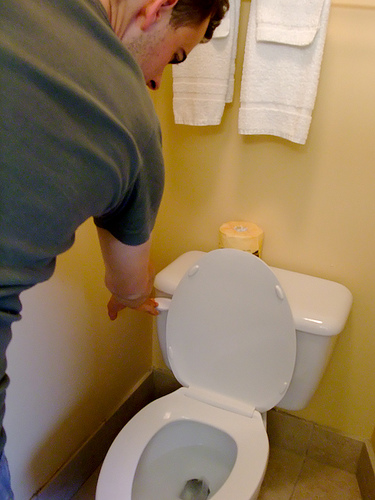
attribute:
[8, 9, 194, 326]
man — flushing, leaning, standing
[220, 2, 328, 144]
towels — white, hanging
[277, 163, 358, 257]
wall — biege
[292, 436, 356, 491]
floor — brown, tile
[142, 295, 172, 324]
handle — white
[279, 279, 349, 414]
water tank — white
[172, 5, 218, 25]
hair — brown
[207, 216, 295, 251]
paper — yellow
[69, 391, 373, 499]
floor — beige, tile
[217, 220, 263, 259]
wrapper — yellow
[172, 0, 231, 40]
hair — brown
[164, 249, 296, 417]
lid — up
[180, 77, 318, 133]
towels — white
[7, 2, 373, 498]
bathroom — small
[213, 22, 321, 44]
washcloths — white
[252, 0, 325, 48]
cloth — white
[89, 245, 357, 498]
toilet — white, stinky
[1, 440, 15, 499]
jeans — blue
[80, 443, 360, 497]
tiled flooring — stone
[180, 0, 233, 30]
hair — little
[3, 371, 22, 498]
jeans — blue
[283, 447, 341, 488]
tile floor — beige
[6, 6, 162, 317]
shirt — green